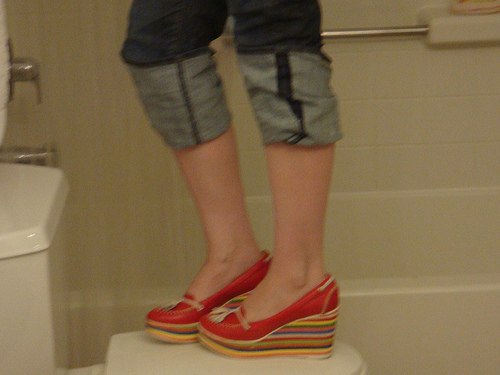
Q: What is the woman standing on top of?
A: Toilet.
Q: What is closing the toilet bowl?
A: Lid.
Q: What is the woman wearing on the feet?
A: Shoes.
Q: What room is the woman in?
A: Bathroom.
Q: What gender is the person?
A: Female.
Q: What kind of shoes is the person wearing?
A: High heel wedges.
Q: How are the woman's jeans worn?
A: Rolled up.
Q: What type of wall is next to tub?
A: Tiles.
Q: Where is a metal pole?
A: Wall along tub.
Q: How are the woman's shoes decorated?
A: Striped.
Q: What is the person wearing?
A: Jeans.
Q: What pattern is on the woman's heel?
A: Horizontal rainbow stripes.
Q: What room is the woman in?
A: The bathroom.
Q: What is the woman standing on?
A: A toilet seat.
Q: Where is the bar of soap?
A: On the wall of the bathtub.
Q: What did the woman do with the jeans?
A: Folded the bottom of the pant legs up.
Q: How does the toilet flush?
A: With the silver handle.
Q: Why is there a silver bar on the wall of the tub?
A: So a person can hold onto it and avoid falling.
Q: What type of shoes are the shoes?
A: Platform shoes.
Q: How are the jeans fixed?
A: Rolled up to calves.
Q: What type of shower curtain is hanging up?
A: Curtain is clear.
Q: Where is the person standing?
A: On toilet.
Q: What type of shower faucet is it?
A: Single lever.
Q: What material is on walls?
A: Tiles.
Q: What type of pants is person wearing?
A: Jeans.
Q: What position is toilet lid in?
A: Lid is down.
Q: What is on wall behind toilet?
A: Toilet tank.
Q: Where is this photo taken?
A: In the bathroom.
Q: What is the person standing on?
A: A toilet.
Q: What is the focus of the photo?
A: The shoes.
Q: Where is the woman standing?
A: Toilet.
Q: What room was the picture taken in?
A: Bathroom.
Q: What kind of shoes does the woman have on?
A: Wedge.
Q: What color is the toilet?
A: White.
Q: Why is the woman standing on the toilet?
A: Short.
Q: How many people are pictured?
A: 1.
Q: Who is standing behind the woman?
A: Nobody.